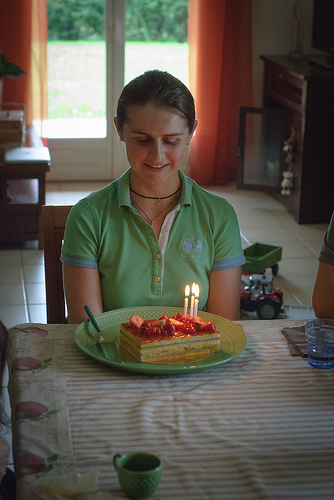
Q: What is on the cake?
A: Candles.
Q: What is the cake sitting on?
A: A plate.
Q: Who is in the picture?
A: A woman enjoying her cake.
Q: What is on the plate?
A: A cake.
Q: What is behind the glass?
A: The backyard,.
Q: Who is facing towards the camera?
A: A brunette smiling woman.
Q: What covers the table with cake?
A: Striped table cloth.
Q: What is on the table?
A: A cake.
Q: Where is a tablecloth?
A: On a table.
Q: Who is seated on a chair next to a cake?
A: A woman wearing a green shirt.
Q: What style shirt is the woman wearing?
A: Polo.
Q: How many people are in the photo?
A: One.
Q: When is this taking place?
A: Daytime.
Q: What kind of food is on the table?
A: Cake.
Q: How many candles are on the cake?
A: Three.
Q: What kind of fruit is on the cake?
A: Strawberries.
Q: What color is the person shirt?
A: Green.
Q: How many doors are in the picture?
A: One.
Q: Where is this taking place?
A: At a dining table.